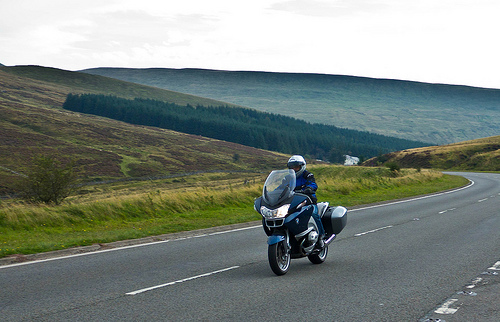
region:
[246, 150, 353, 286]
person on a motorcycle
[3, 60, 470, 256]
grass and trees on the hill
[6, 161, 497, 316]
two lane asphalt road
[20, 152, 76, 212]
small young tree in the grass field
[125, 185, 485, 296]
dotted white lines separating lanes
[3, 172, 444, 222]
high grass by the road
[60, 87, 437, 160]
a section of trees surrounded by grass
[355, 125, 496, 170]
a hill with grass on it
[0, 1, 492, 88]
light sky with a few white clouds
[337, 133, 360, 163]
the other end of the street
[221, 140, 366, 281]
man riding motor cycle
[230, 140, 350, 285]
man wearing a helmet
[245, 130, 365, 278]
man wearing a jacket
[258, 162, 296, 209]
window on a cycle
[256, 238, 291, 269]
tire on a cycle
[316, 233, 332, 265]
tire on a cycle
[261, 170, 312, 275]
cycle on a street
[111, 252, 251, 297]
line on street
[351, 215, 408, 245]
line on a street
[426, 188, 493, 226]
line on a street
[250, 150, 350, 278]
a man on a motorcycle on a highway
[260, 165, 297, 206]
the windshield of a motorcycle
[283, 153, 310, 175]
a motorcycle helmet on a head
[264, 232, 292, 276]
a wheel of a motorcycle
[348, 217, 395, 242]
the white stripe on a highway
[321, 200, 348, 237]
the saddle bag of a motorcycle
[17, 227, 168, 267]
the edge of a highway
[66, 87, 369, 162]
a forest on the side of a hill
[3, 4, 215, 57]
the clouds in the sky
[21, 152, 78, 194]
the leaves of a bush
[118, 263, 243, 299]
white line on road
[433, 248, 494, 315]
white line on road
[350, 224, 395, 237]
white line on road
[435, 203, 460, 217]
white line on road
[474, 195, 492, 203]
white line on road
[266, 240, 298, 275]
round black bike tire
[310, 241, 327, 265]
round black bike tire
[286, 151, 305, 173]
white colored motorcycle helmet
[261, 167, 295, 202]
clear plastic bike windsheild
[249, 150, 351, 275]
man riding on motorcycle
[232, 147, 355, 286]
this is a person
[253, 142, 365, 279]
the person is on a bike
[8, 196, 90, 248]
a patch of grass by the road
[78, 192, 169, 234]
a patch of grass by the road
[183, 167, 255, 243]
a patch of grass by the road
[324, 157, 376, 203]
a patch of grass by the road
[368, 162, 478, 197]
a patch of grass by the road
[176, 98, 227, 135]
these are trees on a hill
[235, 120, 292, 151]
these are trees on a hill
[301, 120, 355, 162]
these are trees on a hill